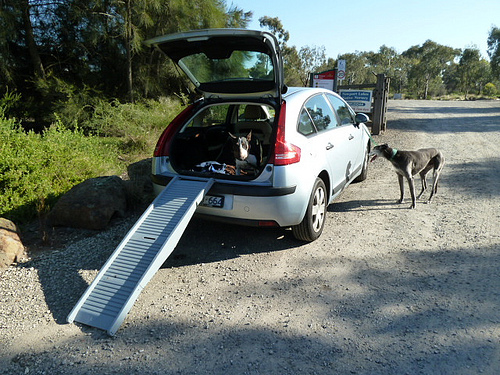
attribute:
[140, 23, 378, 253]
car — open, hatchback, parked, silver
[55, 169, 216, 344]
ramp — narrow, blue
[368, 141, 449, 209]
dog — black, white, gray, greyhound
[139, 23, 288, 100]
door — open, lifted up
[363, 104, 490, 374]
road — gray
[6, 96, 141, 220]
grass — tall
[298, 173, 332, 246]
tire — black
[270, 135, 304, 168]
taillight — red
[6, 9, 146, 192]
area — forested, green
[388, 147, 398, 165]
collar — light green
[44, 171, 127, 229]
rock — large